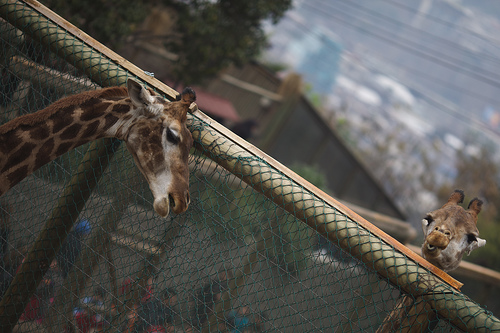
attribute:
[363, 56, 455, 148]
clouds — white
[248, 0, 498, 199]
sky — blue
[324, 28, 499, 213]
clouds — white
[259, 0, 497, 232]
blue sky — blue 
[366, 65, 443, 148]
clouds — white 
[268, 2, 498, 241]
sky — blue 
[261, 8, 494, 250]
sky — blue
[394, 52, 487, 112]
clouds — white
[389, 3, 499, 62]
sky — blue